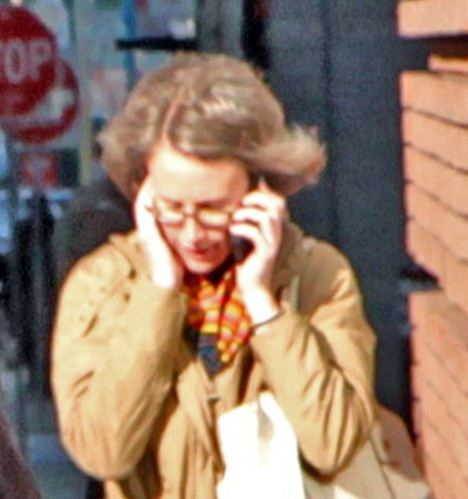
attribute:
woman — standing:
[46, 53, 440, 498]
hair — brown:
[90, 57, 334, 208]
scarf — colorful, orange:
[175, 274, 262, 372]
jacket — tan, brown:
[47, 232, 375, 498]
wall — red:
[383, 2, 466, 470]